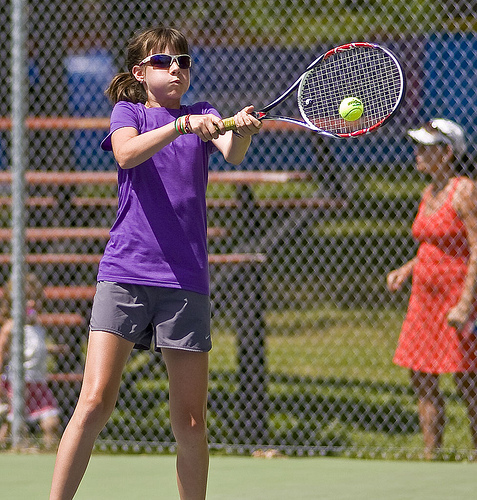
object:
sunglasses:
[138, 51, 196, 76]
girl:
[48, 24, 268, 499]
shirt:
[93, 97, 229, 299]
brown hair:
[102, 24, 190, 111]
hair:
[102, 25, 191, 109]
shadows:
[93, 350, 469, 454]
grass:
[93, 173, 477, 465]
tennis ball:
[338, 94, 365, 125]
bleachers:
[0, 0, 476, 177]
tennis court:
[0, 450, 476, 498]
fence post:
[8, 0, 34, 453]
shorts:
[88, 276, 220, 356]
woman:
[385, 111, 477, 459]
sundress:
[391, 175, 477, 378]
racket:
[212, 42, 410, 142]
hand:
[232, 102, 265, 140]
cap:
[405, 114, 466, 160]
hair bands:
[184, 111, 194, 135]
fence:
[0, 0, 476, 465]